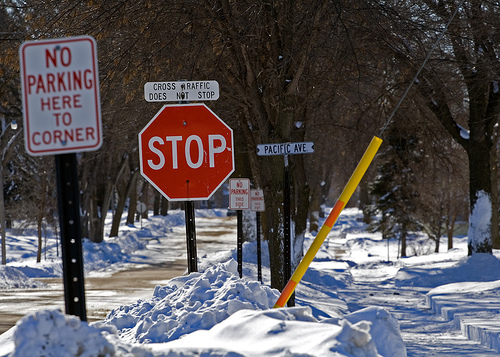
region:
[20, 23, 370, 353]
signs on the side of a road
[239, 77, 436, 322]
a yellow wire protector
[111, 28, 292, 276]
a stop sign is red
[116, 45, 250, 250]
stop signs are octogons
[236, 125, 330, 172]
this sign says pacific ave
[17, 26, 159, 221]
this is a no parking sign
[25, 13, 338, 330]
three no parking signs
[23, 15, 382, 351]
the signs are in deep snow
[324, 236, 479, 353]
the sidewalk needs shoveling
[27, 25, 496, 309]
the season is winter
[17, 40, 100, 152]
This sign clearly warns drivers not to park in certain areas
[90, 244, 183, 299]
Driving on the pavement is much safer than on the snow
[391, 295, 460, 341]
A pathway on sidewalks needs to be clear for walkers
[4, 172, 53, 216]
The winter cold freezes all the leaves off the trees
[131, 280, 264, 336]
This pile of snow looks deep enough to jump in safely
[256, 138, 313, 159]
Everytime there is a Pacific Avenue sign it is natural to look for the ocean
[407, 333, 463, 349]
Packed down snow gets very slippery to walk on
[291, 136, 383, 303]
It is quite possible that a car hit this pole to bend it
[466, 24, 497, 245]
Tree trunks this this are usually a sign of an old tree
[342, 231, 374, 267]
The sunlight on the snow will melt it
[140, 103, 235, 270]
A stop sign in the snow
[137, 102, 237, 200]
The stop sign is an octagon shape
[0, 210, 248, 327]
The street between the snow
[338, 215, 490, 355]
A sidewalk covered in snow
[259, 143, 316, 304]
A street sign above the snow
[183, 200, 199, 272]
A sign post holding the stop sign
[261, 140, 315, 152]
The street sign is rectangular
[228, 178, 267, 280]
No parking signs in the snow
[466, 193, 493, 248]
Snow on the tree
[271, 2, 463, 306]
A power wire above the snow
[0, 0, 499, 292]
the trees are bare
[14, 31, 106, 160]
a read and white no parking sign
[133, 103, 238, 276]
stop sign on a post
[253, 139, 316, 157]
the sign says pacific ave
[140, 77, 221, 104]
a small white sign on top of the stop sign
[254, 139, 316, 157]
the pacific ave sign is white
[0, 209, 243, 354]
the road has snow on it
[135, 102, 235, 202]
letters on the stop sign are white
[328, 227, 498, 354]
the sidewalk is shoveled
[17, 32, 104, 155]
the letters on the no parking sign are red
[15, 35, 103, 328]
red and white sign on a black pole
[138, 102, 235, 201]
red and white octagon shaped sign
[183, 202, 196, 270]
black pole sticking in the snow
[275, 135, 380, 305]
yellow and orange pole sticking in the snow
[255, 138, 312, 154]
black and white street name sign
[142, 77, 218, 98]
black and white sign on top of the stop sign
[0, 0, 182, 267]
tall trees along the roadside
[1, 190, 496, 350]
snow covering the ground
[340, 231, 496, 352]
ice and snow covered sidewalk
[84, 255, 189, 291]
snow cleared pavement